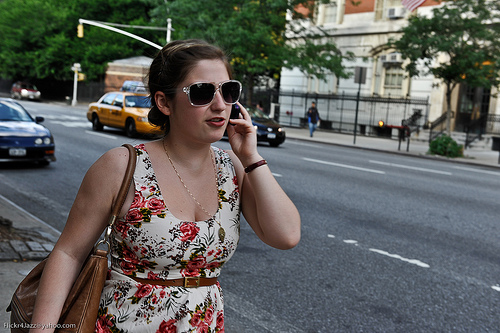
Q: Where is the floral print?
A: Dress.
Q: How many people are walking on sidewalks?
A: Two.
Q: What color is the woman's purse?
A: Brown.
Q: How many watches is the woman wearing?
A: One.